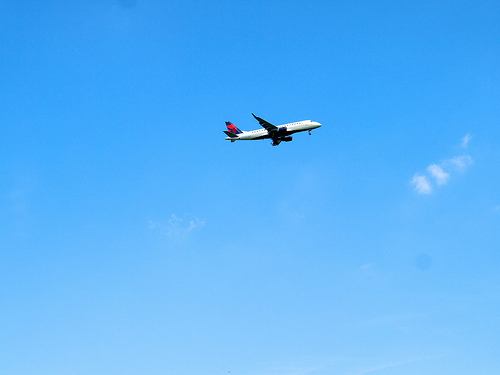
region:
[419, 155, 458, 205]
White cloud in sky.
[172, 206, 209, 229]
White wispy cloud in sky.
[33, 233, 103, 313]
Sky is blue and clear.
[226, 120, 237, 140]
Red markings on back of plane.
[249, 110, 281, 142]
Wing on side of plane.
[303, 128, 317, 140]
Landing gear is down on plane.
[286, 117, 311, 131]
Window on side of plane.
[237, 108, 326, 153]
Plane is mostly white.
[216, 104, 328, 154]
a plane flying to the right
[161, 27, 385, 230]
a plane flying in a blue sky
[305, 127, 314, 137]
the front wheel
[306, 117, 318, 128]
the cockpit of plane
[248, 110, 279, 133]
left wing of plane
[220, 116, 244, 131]
vertical stabilizer is red and blue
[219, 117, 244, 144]
the tail of plane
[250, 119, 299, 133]
windows on side the plane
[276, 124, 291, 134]
an engine in front a wing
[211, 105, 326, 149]
the plane is color gray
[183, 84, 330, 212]
air plane flying in air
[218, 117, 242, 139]
red decal on plane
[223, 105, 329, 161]
plane body is white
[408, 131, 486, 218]
white cloud in sky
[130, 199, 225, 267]
shallow white cloud in sky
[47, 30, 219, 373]
gradient blue sky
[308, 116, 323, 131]
the nose of the plane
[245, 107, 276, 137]
the wing of the plane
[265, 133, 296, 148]
the landing gear of the plane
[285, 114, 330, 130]
the front window of the plane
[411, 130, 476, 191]
a small puffy cloud in front of the plane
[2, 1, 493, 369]
a blue sky high above the airplane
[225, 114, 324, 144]
an airplane flying through the air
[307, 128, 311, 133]
the plane's front landing gear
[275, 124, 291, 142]
the plane's jet engines under wing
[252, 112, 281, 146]
the airplane's wings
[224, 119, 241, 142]
the red and blue tail of the airplane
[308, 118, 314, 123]
the cockpit window of the plane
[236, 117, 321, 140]
the white airplane fuselage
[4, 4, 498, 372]
Plane flying in the sky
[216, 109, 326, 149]
Airplane with red and blue tail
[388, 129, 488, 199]
White very wispy cloud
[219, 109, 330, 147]
Airplane with front wheel down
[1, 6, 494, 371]
Pale blue sky with a few small clouds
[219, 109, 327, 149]
White airplane with blue and red accents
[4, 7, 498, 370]
Airplane flying in a clear sky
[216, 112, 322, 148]
Airplane with one side and bottom visable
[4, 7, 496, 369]
Blue sky at top, white clouds at bottom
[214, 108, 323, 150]
Airplane with nose tilted slightly up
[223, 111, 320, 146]
the airplane is flying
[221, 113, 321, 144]
the airplane is moving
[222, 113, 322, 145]
the airplane is in motion